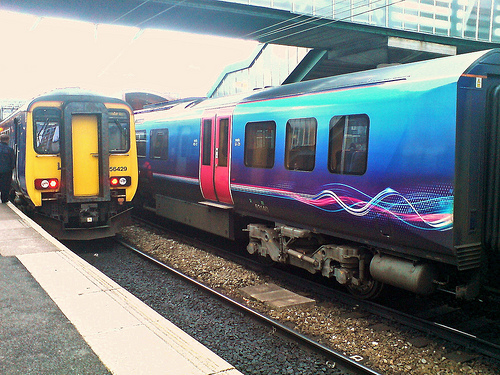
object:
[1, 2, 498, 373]
station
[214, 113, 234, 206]
door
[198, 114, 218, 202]
door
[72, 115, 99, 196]
door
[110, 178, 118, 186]
light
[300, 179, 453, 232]
wave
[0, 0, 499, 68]
bridge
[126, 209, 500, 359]
tracks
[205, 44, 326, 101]
staircase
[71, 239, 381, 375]
tracks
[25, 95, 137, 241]
front of a train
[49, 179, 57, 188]
head lights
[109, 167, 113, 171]
black numbers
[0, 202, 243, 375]
cement train platfor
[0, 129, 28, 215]
passenger boarding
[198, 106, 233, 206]
two door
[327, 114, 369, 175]
passengers window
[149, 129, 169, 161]
passengers window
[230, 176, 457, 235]
colorful paint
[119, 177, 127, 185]
lights on back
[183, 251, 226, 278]
gravel between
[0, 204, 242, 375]
cement sidewalk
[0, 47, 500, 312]
two trains on tracks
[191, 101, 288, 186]
pink and blue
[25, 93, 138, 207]
yellow rear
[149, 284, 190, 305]
brown dirt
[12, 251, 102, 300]
brown bricks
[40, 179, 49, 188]
headlights on train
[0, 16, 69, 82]
bright grey sky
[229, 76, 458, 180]
blue wall on train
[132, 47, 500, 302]
purple and blue trai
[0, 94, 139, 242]
black train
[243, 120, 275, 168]
glass windows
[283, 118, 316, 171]
glass window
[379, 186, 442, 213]
blue metal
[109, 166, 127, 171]
number decal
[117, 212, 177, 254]
gravel between